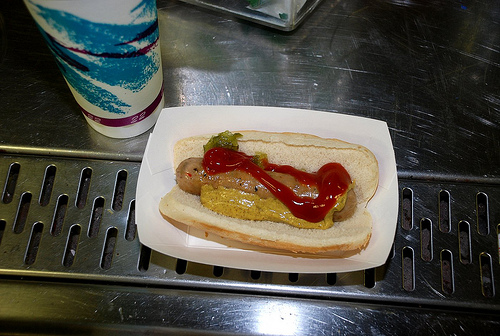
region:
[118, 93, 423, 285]
a small paper carton on the counter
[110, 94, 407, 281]
the paper carton is white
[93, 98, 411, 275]
a hotdog in the paper carton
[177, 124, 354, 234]
ketchup is on the hotdog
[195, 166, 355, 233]
mustard is on the hotdog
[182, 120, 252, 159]
relish is on the hotdog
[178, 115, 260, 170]
the relish is green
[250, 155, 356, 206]
the ketchup is red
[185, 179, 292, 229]
the mustard is yellow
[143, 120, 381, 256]
the hotdog bun is white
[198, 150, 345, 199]
red ketchup on top of sausage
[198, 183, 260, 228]
spicy yellow mustard on sausage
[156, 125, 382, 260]
white bread on bun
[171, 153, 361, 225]
sausage in white hot dog bun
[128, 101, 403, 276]
paper container for sausage dog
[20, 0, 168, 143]
white, blue, and purple paper cup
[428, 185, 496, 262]
holes in metal countertop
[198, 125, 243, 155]
green relish on top of sausage dog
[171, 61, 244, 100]
light reflecting on countertop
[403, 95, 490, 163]
line marks on counter top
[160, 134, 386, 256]
hot dog on white plate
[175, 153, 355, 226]
wienner on a hot dog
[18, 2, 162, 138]
blue and white cup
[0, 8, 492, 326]
metal table behind white plate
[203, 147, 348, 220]
ketchup on hot dog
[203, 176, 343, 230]
mustard on hot dog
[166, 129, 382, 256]
hot dog with mustard and ketchup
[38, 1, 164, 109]
blue lines in white cup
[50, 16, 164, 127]
wine lines in white cup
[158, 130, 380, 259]
fast food on white plate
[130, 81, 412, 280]
hotdog in white container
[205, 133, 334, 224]
red ketchup on brownish hotdog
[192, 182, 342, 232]
yellow mustard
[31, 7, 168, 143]
paper cup with blue desgn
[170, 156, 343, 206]
hotdog covered with mustard and ketchup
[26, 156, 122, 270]
chrome gete with holes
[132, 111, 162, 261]
edge of white paper container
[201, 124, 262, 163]
relish on side of hotdog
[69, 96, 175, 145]
purple stripe base of cup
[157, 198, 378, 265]
white bun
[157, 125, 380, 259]
The sausage is in a bun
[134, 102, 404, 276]
The food is in a paper container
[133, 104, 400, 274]
The meat has relish on it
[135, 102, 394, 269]
The meat has ketchup on it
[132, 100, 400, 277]
The meat has mustard on it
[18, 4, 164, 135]
There is a cup next to the food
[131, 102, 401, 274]
The food is on a metal table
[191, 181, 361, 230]
The mustard is spicy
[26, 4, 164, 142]
The cup is three different colors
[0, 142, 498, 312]
There are holes in the table